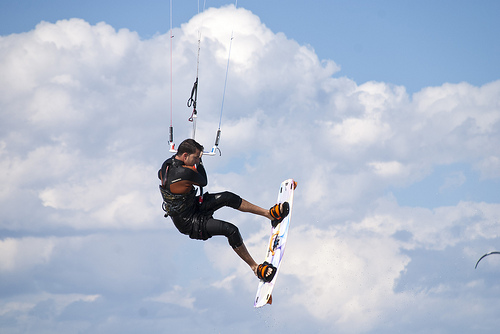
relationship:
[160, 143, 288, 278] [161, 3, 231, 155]
man holds ropes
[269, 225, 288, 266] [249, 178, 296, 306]
graffiti on surfboard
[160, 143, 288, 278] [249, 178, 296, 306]
man on surfboard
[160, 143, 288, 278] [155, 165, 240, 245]
man wears clothing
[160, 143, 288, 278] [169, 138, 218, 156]
man holds bar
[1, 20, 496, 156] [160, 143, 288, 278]
clouds behind man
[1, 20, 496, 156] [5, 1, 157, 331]
clouds in sky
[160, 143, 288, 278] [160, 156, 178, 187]
man wears harness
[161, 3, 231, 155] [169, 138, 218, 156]
ropes attached to bar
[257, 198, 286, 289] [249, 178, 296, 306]
feet on surfboard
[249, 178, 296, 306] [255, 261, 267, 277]
surfboard has straps